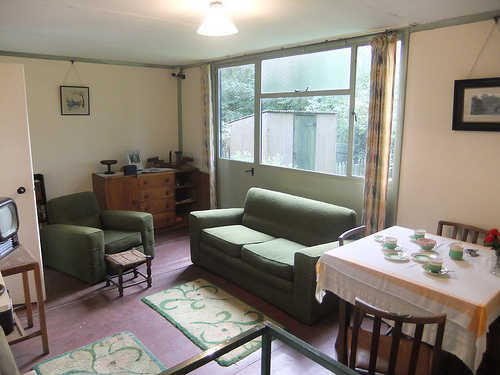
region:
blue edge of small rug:
[137, 293, 204, 337]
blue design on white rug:
[172, 290, 231, 332]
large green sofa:
[195, 172, 360, 297]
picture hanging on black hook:
[53, 64, 110, 127]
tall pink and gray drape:
[355, 29, 391, 229]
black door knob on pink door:
[11, 182, 43, 203]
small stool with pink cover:
[89, 240, 165, 287]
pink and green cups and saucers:
[373, 225, 468, 273]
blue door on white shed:
[283, 104, 333, 177]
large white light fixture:
[192, 6, 274, 56]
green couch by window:
[206, 183, 317, 289]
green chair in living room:
[50, 195, 144, 265]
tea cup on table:
[421, 254, 448, 276]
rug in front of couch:
[162, 272, 252, 355]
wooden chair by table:
[347, 301, 442, 369]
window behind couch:
[222, 70, 379, 177]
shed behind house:
[240, 103, 345, 168]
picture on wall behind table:
[442, 71, 497, 159]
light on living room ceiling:
[195, 14, 253, 48]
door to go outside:
[220, 76, 256, 196]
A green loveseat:
[187, 186, 359, 325]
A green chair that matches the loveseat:
[37, 189, 155, 283]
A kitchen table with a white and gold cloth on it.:
[319, 224, 499, 363]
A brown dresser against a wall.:
[132, 166, 179, 234]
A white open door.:
[2, 63, 46, 307]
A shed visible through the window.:
[225, 107, 340, 179]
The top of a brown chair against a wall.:
[432, 219, 494, 246]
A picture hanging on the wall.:
[58, 57, 91, 117]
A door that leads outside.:
[207, 56, 261, 220]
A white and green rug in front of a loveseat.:
[140, 274, 285, 366]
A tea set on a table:
[351, 210, 494, 305]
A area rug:
[143, 265, 273, 369]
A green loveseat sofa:
[176, 162, 384, 336]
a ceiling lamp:
[176, 5, 261, 45]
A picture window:
[192, 50, 406, 189]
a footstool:
[85, 235, 175, 295]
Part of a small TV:
[0, 190, 30, 262]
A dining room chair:
[339, 291, 444, 373]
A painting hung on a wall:
[45, 77, 110, 119]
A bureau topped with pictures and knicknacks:
[81, 150, 216, 235]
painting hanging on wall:
[55, 79, 97, 116]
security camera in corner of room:
[164, 61, 191, 81]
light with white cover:
[181, 0, 253, 50]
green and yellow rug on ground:
[144, 270, 252, 330]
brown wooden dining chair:
[333, 294, 447, 373]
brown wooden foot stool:
[99, 240, 159, 297]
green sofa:
[184, 179, 331, 314]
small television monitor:
[0, 193, 30, 254]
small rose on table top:
[484, 226, 498, 277]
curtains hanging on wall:
[359, 36, 407, 211]